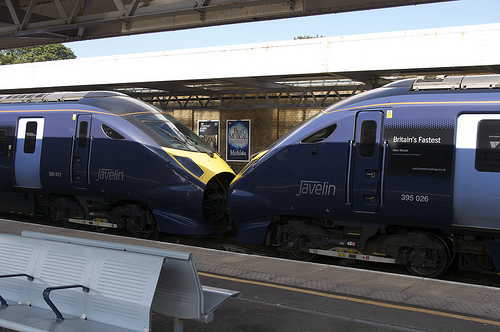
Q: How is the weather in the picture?
A: It is clear.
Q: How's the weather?
A: It is clear.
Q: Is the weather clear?
A: Yes, it is clear.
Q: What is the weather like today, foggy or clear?
A: It is clear.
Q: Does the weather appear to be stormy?
A: No, it is clear.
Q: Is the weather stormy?
A: No, it is clear.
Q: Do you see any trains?
A: Yes, there is a train.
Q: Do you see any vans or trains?
A: Yes, there is a train.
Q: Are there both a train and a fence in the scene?
A: No, there is a train but no fences.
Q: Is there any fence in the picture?
A: No, there are no fences.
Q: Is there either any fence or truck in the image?
A: No, there are no fences or trucks.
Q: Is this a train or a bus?
A: This is a train.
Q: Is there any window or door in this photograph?
A: Yes, there are doors.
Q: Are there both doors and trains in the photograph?
A: Yes, there are both doors and a train.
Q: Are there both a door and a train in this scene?
A: Yes, there are both a door and a train.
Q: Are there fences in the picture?
A: No, there are no fences.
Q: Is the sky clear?
A: Yes, the sky is clear.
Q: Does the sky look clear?
A: Yes, the sky is clear.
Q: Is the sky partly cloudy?
A: No, the sky is clear.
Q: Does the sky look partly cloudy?
A: No, the sky is clear.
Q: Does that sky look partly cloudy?
A: No, the sky is clear.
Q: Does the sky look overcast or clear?
A: The sky is clear.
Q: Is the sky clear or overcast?
A: The sky is clear.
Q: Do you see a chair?
A: No, there are no chairs.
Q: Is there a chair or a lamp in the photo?
A: No, there are no chairs or lamps.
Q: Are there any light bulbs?
A: No, there are no light bulbs.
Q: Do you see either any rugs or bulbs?
A: No, there are no bulbs or rugs.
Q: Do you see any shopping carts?
A: No, there are no shopping carts.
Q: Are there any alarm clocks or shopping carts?
A: No, there are no shopping carts or alarm clocks.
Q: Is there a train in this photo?
A: Yes, there is a train.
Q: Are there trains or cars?
A: Yes, there is a train.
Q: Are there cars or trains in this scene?
A: Yes, there is a train.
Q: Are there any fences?
A: No, there are no fences.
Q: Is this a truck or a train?
A: This is a train.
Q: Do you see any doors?
A: Yes, there is a door.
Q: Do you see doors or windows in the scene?
A: Yes, there is a door.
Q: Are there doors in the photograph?
A: Yes, there is a door.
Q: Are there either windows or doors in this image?
A: Yes, there is a door.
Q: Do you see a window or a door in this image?
A: Yes, there is a door.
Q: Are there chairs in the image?
A: No, there are no chairs.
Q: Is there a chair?
A: No, there are no chairs.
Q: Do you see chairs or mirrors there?
A: No, there are no chairs or mirrors.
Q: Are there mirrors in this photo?
A: No, there are no mirrors.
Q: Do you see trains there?
A: Yes, there is a train.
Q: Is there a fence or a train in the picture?
A: Yes, there is a train.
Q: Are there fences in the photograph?
A: No, there are no fences.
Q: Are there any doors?
A: Yes, there is a door.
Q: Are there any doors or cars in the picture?
A: Yes, there is a door.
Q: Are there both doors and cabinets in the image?
A: No, there is a door but no cabinets.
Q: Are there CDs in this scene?
A: No, there are no cds.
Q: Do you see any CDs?
A: No, there are no cds.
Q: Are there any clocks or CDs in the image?
A: No, there are no CDs or clocks.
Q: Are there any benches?
A: Yes, there is a bench.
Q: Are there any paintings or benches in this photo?
A: Yes, there is a bench.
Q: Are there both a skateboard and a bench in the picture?
A: No, there is a bench but no skateboards.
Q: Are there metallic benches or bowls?
A: Yes, there is a metal bench.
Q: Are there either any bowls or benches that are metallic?
A: Yes, the bench is metallic.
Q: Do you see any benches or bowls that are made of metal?
A: Yes, the bench is made of metal.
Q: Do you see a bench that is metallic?
A: Yes, there is a metal bench.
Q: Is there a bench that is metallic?
A: Yes, there is a bench that is metallic.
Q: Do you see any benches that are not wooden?
A: Yes, there is a metallic bench.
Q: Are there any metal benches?
A: Yes, there is a bench that is made of metal.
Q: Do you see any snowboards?
A: No, there are no snowboards.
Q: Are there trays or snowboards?
A: No, there are no snowboards or trays.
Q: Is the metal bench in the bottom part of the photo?
A: Yes, the bench is in the bottom of the image.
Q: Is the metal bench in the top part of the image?
A: No, the bench is in the bottom of the image.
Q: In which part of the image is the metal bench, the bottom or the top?
A: The bench is in the bottom of the image.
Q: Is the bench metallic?
A: Yes, the bench is metallic.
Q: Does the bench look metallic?
A: Yes, the bench is metallic.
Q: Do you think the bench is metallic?
A: Yes, the bench is metallic.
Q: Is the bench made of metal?
A: Yes, the bench is made of metal.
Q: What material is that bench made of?
A: The bench is made of metal.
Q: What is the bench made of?
A: The bench is made of metal.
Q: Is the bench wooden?
A: No, the bench is metallic.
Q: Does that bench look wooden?
A: No, the bench is metallic.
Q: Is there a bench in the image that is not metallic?
A: No, there is a bench but it is metallic.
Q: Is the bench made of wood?
A: No, the bench is made of metal.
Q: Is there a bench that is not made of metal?
A: No, there is a bench but it is made of metal.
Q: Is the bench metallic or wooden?
A: The bench is metallic.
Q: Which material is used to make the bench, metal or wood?
A: The bench is made of metal.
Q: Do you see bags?
A: No, there are no bags.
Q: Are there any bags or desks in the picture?
A: No, there are no bags or desks.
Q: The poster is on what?
A: The poster is on the wall.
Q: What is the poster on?
A: The poster is on the wall.